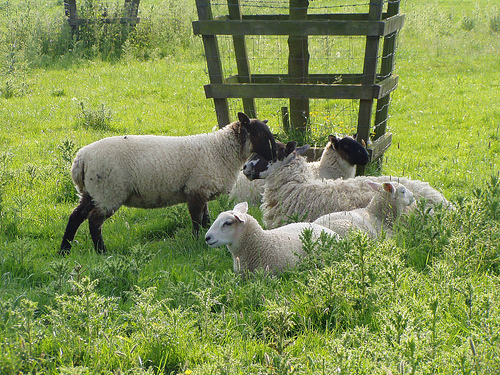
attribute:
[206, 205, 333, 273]
sheep — Black 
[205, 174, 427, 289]
sheep — White 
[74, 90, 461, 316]
sheep — close together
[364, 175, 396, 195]
ears — white 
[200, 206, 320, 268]
sheep — white , Black 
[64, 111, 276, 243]
sheep — Black 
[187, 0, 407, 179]
object — wooden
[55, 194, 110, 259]
legs — black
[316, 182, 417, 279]
sheep — white 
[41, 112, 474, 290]
sheep — group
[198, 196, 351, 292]
sheep — laying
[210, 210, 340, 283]
sheep — White 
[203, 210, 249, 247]
head — white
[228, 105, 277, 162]
head — Black 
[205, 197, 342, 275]
sheep — white, closest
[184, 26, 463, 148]
wooden boards — several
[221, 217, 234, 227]
eye — Black 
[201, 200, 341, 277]
closest sheep — white 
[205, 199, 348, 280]
sheep — White 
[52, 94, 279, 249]
sheep — Black 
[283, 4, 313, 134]
trunk — brown 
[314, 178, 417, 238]
sheep — small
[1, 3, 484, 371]
weeds — tall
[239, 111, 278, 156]
face — black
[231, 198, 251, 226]
ears — flat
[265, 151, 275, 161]
nose — black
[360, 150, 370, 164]
nose — black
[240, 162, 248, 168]
nose — black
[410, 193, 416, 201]
nose — black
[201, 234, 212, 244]
nose — black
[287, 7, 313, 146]
trunk — tree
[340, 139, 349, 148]
eye — black